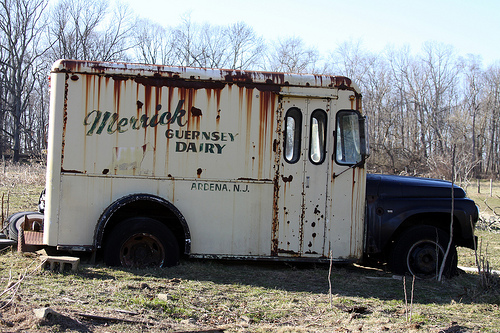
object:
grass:
[0, 159, 499, 333]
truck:
[41, 58, 479, 278]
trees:
[0, 0, 499, 179]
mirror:
[333, 108, 366, 166]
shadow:
[48, 256, 500, 306]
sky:
[3, 0, 499, 109]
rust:
[62, 60, 282, 179]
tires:
[102, 214, 179, 269]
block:
[41, 256, 80, 273]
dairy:
[175, 141, 226, 153]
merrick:
[84, 99, 188, 137]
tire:
[6, 210, 44, 242]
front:
[364, 172, 480, 278]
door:
[276, 94, 328, 259]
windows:
[283, 106, 328, 164]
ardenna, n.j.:
[190, 182, 250, 192]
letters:
[83, 98, 248, 192]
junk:
[1, 212, 81, 270]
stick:
[0, 254, 48, 310]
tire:
[392, 223, 457, 277]